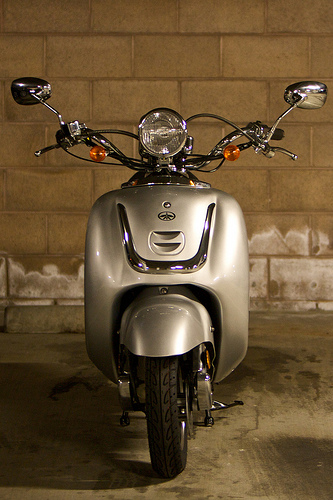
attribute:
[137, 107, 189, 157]
headlight — big, round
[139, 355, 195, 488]
tire — black, rubber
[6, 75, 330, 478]
motorcycle — parked, silver, gray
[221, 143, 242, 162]
light — yellow, orange, circle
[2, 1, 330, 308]
wall — brick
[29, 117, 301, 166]
handlebars — chrome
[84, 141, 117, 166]
signal — orange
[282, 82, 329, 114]
mirror — silver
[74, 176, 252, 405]
trim — silver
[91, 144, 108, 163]
light — orange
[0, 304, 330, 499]
ground — concrete, dirty